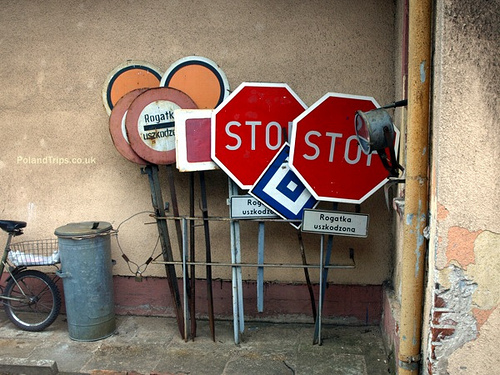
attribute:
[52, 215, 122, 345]
trash can — grey, cylindrical, trash bin, dark blue, slate blue, metal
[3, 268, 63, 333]
wheel — rear wheel, rubber, black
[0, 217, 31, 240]
seat — black, bicycle seat, triangularish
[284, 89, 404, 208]
stop sign — red, roadless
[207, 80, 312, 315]
stop sign — in middle, road sign, roadless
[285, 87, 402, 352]
stop sign — road sign, roadless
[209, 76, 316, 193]
stop sign — red, roadless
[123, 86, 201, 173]
sign — round, red, white, red+white, circular, faded red+white, road sign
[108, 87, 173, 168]
sign — round, red, white, red+white, circular, faded red+white, road sign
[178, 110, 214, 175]
sign — rectangular, red, white, white+red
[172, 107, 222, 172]
sign — rectangular, red, white, white+red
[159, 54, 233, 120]
sign — circular, orange, white, black, orange+black+white, grubby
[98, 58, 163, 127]
sign — circular, orange, white, black, orange+black+white, grubby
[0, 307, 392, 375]
sidewalk — floor, grey, concrete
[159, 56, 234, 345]
sign — orange+black+white, road sign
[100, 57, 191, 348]
sign — orange+black+white, road sign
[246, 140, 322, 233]
sign — blue, white, blue+white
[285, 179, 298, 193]
central diamond — white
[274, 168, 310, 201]
second inner diamond — blue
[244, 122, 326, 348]
sign — diamond-shaped, road sign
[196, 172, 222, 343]
post — dark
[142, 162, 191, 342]
post — dark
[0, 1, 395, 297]
wall — light brown, grimy, damaged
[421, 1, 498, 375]
wall — grimy, light brown, cracking, damaged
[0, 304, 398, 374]
street — dark silver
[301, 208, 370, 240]
sign — white, rectangular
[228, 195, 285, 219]
sign — white, rectangular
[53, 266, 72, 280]
handle — small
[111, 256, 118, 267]
handle — small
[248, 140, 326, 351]
road sign — refuse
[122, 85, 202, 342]
road sign — refuse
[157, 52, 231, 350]
road sign — refuse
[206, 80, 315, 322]
road sign — refuse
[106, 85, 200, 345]
road sign — refuse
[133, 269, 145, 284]
lock — padlock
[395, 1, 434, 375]
pipe — drainage pipe, yellow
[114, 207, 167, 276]
chain — connecting wire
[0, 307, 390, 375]
pavement — gritty, grimy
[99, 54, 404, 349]
signs — nine, leaning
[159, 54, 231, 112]
rim — decaying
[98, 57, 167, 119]
rim — decaying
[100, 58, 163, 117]
border — grubby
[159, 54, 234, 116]
border — grubby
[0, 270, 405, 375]
bricks — decaying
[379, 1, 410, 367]
wall — damaged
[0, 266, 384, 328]
wall — damaged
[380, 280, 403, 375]
wall — damaged